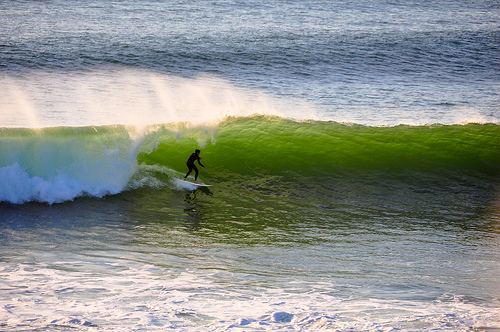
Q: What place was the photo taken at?
A: It was taken at the ocean.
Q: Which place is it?
A: It is an ocean.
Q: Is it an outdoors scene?
A: Yes, it is outdoors.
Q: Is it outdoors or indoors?
A: It is outdoors.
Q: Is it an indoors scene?
A: No, it is outdoors.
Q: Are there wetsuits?
A: Yes, there is a wetsuit.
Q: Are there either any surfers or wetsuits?
A: Yes, there is a wetsuit.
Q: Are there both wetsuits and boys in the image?
A: No, there is a wetsuit but no boys.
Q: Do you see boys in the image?
A: No, there are no boys.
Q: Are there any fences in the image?
A: No, there are no fences.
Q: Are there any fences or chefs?
A: No, there are no fences or chefs.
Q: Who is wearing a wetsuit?
A: The man is wearing a wetsuit.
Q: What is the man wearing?
A: The man is wearing a wetsuit.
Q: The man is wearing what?
A: The man is wearing a wetsuit.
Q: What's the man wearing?
A: The man is wearing a wetsuit.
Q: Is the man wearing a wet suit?
A: Yes, the man is wearing a wet suit.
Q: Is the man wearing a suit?
A: No, the man is wearing a wet suit.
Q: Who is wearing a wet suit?
A: The man is wearing a wet suit.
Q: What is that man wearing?
A: The man is wearing a wetsuit.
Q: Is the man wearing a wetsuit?
A: Yes, the man is wearing a wetsuit.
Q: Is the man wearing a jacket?
A: No, the man is wearing a wetsuit.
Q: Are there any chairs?
A: No, there are no chairs.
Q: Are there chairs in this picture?
A: No, there are no chairs.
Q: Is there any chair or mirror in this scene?
A: No, there are no chairs or mirrors.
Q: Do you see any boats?
A: No, there are no boats.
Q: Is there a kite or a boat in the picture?
A: No, there are no boats or kites.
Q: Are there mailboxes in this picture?
A: No, there are no mailboxes.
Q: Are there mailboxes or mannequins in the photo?
A: No, there are no mailboxes or mannequins.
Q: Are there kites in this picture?
A: No, there are no kites.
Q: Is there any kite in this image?
A: No, there are no kites.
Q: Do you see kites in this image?
A: No, there are no kites.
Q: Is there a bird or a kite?
A: No, there are no kites or birds.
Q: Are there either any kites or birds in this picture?
A: No, there are no kites or birds.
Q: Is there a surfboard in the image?
A: Yes, there is a surfboard.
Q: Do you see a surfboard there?
A: Yes, there is a surfboard.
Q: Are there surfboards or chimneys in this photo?
A: Yes, there is a surfboard.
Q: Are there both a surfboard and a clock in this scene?
A: No, there is a surfboard but no clocks.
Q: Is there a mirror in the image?
A: No, there are no mirrors.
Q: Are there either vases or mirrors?
A: No, there are no mirrors or vases.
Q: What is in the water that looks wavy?
A: The surfboard is in the water.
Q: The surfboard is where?
A: The surfboard is in the water.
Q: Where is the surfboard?
A: The surfboard is in the water.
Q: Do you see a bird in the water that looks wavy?
A: No, there is a surfboard in the water.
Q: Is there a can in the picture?
A: No, there are no cans.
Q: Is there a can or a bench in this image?
A: No, there are no cans or benches.